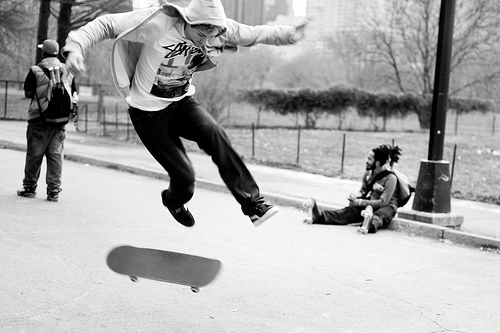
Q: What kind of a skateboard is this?
A: Black.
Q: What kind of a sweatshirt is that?
A: Gray.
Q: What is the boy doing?
A: Skateboarding.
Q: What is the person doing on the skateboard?
A: Jumping in the air.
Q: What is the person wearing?
A: Sweatjacket.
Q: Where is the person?
A: Park.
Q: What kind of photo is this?
A: Black and white.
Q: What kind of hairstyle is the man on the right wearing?
A: Dreads.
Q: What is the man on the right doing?
A: Sitting on the sidewalk.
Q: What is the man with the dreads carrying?
A: Backpack.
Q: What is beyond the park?
A: Buildings.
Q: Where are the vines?
A: On the fence.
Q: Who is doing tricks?
A: Man in the air.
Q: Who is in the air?
A: Man in dark pants.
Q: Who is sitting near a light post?
A: Man with ponytail.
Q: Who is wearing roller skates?
A: Man sitting.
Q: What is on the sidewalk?
A: Street post.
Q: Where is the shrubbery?
A: On the fence.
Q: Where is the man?
A: Sidewalk.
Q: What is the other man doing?
A: Jumping.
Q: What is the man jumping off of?
A: Skateboard.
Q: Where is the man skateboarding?
A: On the street.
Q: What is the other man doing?
A: Walking.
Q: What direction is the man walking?
A: Left.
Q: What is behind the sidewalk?
A: Park.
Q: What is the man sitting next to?
A: Pole.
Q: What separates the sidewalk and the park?
A: Fence.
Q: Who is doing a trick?
A: A skateboarder.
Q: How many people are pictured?
A: Three.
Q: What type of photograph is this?
A: Black and white.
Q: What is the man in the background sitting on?
A: A curb.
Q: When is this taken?
A: Daytime.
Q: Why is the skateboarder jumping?
A: He is doing a trick.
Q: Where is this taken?
A: A park.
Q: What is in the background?
A: A city.